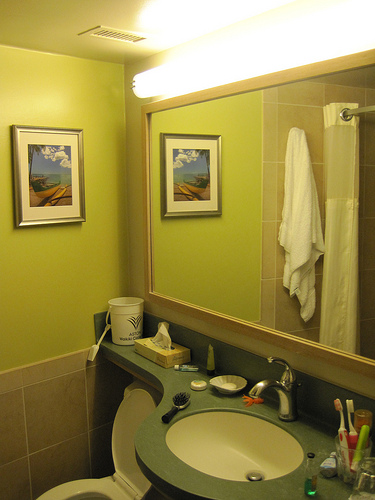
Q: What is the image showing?
A: It is showing a bathroom.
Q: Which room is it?
A: It is a bathroom.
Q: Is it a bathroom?
A: Yes, it is a bathroom.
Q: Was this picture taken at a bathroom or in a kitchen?
A: It was taken at a bathroom.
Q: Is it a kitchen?
A: No, it is a bathroom.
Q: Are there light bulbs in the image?
A: No, there are no light bulbs.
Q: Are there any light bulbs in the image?
A: No, there are no light bulbs.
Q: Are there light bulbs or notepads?
A: No, there are no light bulbs or notepads.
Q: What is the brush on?
A: The brush is on the counter.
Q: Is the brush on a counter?
A: Yes, the brush is on a counter.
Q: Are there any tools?
A: No, there are no tools.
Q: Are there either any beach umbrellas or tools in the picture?
A: No, there are no tools or beach umbrellas.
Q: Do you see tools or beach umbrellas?
A: No, there are no tools or beach umbrellas.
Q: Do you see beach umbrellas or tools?
A: No, there are no tools or beach umbrellas.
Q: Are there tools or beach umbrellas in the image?
A: No, there are no tools or beach umbrellas.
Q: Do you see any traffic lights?
A: No, there are no traffic lights.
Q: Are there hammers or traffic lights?
A: No, there are no traffic lights or hammers.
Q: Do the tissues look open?
A: Yes, the tissues are open.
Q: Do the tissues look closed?
A: No, the tissues are open.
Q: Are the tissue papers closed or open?
A: The tissue papers are open.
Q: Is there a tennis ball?
A: No, there are no tennis balls.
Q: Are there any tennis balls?
A: No, there are no tennis balls.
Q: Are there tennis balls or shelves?
A: No, there are no tennis balls or shelves.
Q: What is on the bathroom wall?
A: The picture is on the wall.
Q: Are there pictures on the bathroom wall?
A: Yes, there is a picture on the wall.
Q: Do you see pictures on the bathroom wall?
A: Yes, there is a picture on the wall.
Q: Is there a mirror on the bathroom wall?
A: No, there is a picture on the wall.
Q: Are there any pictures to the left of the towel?
A: Yes, there is a picture to the left of the towel.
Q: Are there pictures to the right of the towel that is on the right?
A: No, the picture is to the left of the towel.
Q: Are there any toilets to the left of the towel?
A: No, there is a picture to the left of the towel.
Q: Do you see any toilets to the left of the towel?
A: No, there is a picture to the left of the towel.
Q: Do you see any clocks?
A: No, there are no clocks.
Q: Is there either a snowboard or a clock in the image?
A: No, there are no clocks or snowboards.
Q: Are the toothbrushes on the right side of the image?
A: Yes, the toothbrushes are on the right of the image.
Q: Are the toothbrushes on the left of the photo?
A: No, the toothbrushes are on the right of the image.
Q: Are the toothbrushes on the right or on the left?
A: The toothbrushes are on the right of the image.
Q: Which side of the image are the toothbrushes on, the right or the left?
A: The toothbrushes are on the right of the image.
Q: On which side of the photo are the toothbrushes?
A: The toothbrushes are on the right of the image.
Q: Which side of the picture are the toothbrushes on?
A: The toothbrushes are on the right of the image.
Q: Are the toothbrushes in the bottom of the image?
A: Yes, the toothbrushes are in the bottom of the image.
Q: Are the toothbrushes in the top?
A: No, the toothbrushes are in the bottom of the image.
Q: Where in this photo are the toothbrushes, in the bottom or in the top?
A: The toothbrushes are in the bottom of the image.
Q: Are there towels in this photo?
A: Yes, there is a towel.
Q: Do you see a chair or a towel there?
A: Yes, there is a towel.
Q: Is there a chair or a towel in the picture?
A: Yes, there is a towel.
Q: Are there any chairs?
A: No, there are no chairs.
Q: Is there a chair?
A: No, there are no chairs.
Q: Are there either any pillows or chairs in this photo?
A: No, there are no chairs or pillows.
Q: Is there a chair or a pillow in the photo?
A: No, there are no chairs or pillows.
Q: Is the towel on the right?
A: Yes, the towel is on the right of the image.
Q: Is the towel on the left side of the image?
A: No, the towel is on the right of the image.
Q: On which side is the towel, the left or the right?
A: The towel is on the right of the image.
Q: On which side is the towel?
A: The towel is on the right of the image.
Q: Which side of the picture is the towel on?
A: The towel is on the right of the image.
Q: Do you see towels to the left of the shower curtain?
A: Yes, there is a towel to the left of the shower curtain.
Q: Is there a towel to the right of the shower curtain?
A: No, the towel is to the left of the shower curtain.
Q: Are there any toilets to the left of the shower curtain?
A: No, there is a towel to the left of the shower curtain.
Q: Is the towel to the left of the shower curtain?
A: Yes, the towel is to the left of the shower curtain.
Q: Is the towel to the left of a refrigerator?
A: No, the towel is to the left of the shower curtain.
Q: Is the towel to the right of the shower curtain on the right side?
A: No, the towel is to the left of the shower curtain.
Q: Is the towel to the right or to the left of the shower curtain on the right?
A: The towel is to the left of the shower curtain.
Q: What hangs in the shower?
A: The towel hangs in the shower.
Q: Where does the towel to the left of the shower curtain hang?
A: The towel hangs in the shower.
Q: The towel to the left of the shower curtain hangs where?
A: The towel hangs in the shower.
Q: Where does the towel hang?
A: The towel hangs in the shower.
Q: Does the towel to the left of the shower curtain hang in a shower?
A: Yes, the towel hangs in a shower.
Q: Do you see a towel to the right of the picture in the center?
A: Yes, there is a towel to the right of the picture.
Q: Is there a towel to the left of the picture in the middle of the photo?
A: No, the towel is to the right of the picture.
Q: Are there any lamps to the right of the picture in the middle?
A: No, there is a towel to the right of the picture.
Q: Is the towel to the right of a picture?
A: Yes, the towel is to the right of a picture.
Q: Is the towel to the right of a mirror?
A: No, the towel is to the right of a picture.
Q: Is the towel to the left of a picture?
A: No, the towel is to the right of a picture.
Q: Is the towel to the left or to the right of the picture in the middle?
A: The towel is to the right of the picture.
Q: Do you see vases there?
A: No, there are no vases.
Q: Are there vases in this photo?
A: No, there are no vases.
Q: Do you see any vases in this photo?
A: No, there are no vases.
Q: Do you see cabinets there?
A: No, there are no cabinets.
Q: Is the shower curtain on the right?
A: Yes, the shower curtain is on the right of the image.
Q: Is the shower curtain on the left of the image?
A: No, the shower curtain is on the right of the image.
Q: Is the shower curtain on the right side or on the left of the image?
A: The shower curtain is on the right of the image.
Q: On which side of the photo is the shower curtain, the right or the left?
A: The shower curtain is on the right of the image.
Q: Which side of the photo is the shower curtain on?
A: The shower curtain is on the right of the image.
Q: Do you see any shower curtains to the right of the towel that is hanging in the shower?
A: Yes, there is a shower curtain to the right of the towel.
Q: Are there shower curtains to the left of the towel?
A: No, the shower curtain is to the right of the towel.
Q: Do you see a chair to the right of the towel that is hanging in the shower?
A: No, there is a shower curtain to the right of the towel.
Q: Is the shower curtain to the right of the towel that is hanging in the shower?
A: Yes, the shower curtain is to the right of the towel.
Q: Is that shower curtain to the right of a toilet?
A: No, the shower curtain is to the right of the towel.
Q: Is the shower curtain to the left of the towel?
A: No, the shower curtain is to the right of the towel.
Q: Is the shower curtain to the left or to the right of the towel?
A: The shower curtain is to the right of the towel.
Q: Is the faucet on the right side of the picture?
A: Yes, the faucet is on the right of the image.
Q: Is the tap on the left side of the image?
A: No, the tap is on the right of the image.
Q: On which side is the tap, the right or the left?
A: The tap is on the right of the image.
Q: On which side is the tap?
A: The tap is on the right of the image.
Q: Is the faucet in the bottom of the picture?
A: Yes, the faucet is in the bottom of the image.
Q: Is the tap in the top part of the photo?
A: No, the tap is in the bottom of the image.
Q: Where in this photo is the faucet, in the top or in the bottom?
A: The faucet is in the bottom of the image.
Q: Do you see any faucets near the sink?
A: Yes, there is a faucet near the sink.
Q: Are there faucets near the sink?
A: Yes, there is a faucet near the sink.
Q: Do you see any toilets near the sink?
A: No, there is a faucet near the sink.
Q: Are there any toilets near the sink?
A: No, there is a faucet near the sink.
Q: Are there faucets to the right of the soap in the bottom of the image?
A: Yes, there is a faucet to the right of the soap.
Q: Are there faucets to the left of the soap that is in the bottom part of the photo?
A: No, the faucet is to the right of the soap.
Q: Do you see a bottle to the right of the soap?
A: No, there is a faucet to the right of the soap.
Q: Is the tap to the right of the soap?
A: Yes, the tap is to the right of the soap.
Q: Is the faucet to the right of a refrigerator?
A: No, the faucet is to the right of the soap.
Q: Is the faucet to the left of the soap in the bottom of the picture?
A: No, the faucet is to the right of the soap.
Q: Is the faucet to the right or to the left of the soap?
A: The faucet is to the right of the soap.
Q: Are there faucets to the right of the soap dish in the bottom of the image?
A: Yes, there is a faucet to the right of the soap dish.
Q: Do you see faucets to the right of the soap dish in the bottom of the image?
A: Yes, there is a faucet to the right of the soap dish.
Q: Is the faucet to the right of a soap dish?
A: Yes, the faucet is to the right of a soap dish.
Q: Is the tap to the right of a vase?
A: No, the tap is to the right of a soap dish.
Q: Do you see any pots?
A: No, there are no pots.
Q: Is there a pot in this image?
A: No, there are no pots.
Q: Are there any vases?
A: No, there are no vases.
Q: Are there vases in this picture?
A: No, there are no vases.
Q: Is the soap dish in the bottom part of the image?
A: Yes, the soap dish is in the bottom of the image.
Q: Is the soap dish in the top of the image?
A: No, the soap dish is in the bottom of the image.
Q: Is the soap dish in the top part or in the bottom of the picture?
A: The soap dish is in the bottom of the image.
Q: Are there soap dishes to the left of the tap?
A: Yes, there is a soap dish to the left of the tap.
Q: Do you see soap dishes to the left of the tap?
A: Yes, there is a soap dish to the left of the tap.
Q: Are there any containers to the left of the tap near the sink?
A: No, there is a soap dish to the left of the tap.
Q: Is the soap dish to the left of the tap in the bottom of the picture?
A: Yes, the soap dish is to the left of the faucet.